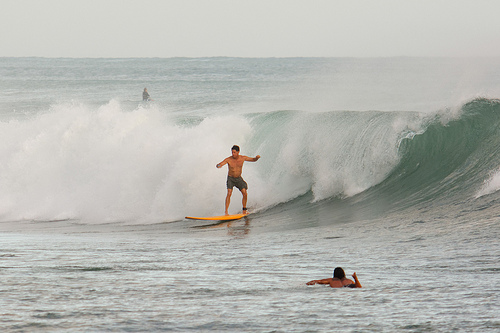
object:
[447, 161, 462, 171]
ground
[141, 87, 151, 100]
person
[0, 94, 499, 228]
large wave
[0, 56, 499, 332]
ocean water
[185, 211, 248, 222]
board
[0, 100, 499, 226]
wave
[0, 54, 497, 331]
ocean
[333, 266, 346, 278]
hair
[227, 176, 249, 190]
short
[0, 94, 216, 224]
spray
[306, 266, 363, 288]
man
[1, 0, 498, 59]
cloudy sky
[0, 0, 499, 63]
clouds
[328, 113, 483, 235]
ocean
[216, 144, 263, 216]
he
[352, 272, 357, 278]
foot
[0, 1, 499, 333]
air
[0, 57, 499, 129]
distance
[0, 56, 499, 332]
water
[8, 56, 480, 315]
ocean